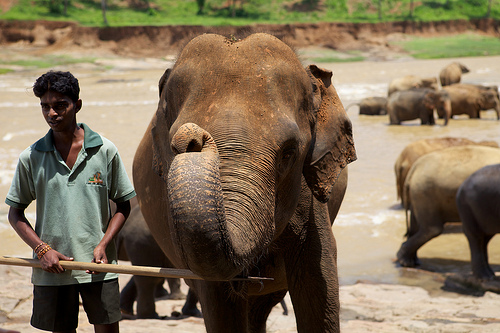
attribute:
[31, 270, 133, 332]
shorts — black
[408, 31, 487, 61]
grass — green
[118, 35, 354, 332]
elephant — grey, large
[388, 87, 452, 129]
elephant — large, gray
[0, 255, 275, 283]
stick — long, wooden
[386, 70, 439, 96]
elephant — large, grey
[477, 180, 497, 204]
grey — large grey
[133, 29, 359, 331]
elephant — small, grey, large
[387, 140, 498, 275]
elephant — large, grey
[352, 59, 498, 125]
elephants — herd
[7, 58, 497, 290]
water — muddy